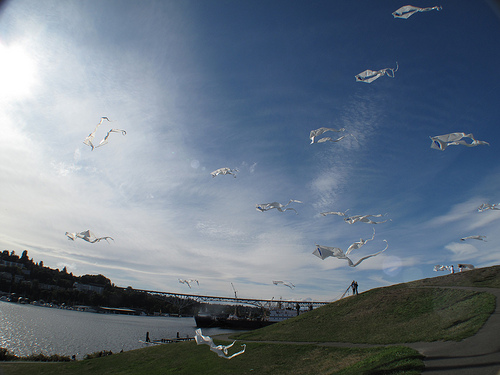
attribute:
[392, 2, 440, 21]
kite — white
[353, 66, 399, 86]
kite — white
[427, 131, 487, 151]
kite — white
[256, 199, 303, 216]
kite — white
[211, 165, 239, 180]
kite — white